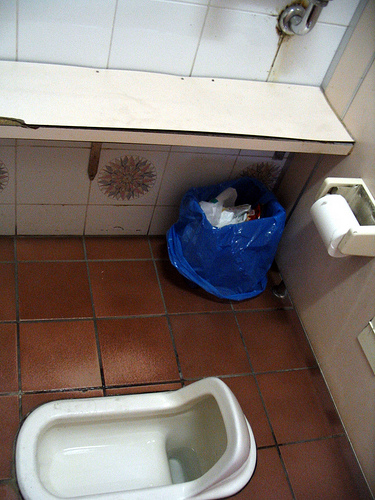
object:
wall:
[270, 0, 373, 499]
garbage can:
[167, 177, 286, 302]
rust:
[279, 3, 306, 38]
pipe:
[278, 0, 331, 38]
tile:
[17, 0, 114, 69]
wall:
[0, 0, 363, 232]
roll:
[310, 192, 360, 256]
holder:
[318, 172, 375, 259]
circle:
[95, 153, 159, 203]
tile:
[85, 143, 174, 211]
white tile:
[189, 7, 284, 82]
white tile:
[268, 18, 349, 86]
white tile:
[104, 0, 207, 77]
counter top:
[0, 43, 354, 158]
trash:
[197, 181, 260, 230]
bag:
[164, 176, 287, 301]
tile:
[87, 257, 168, 320]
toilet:
[13, 372, 259, 500]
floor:
[0, 234, 167, 393]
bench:
[0, 55, 355, 158]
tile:
[94, 311, 184, 390]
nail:
[211, 78, 215, 83]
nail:
[180, 76, 185, 81]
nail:
[94, 68, 101, 74]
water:
[166, 446, 201, 484]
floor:
[0, 235, 375, 500]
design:
[95, 153, 161, 206]